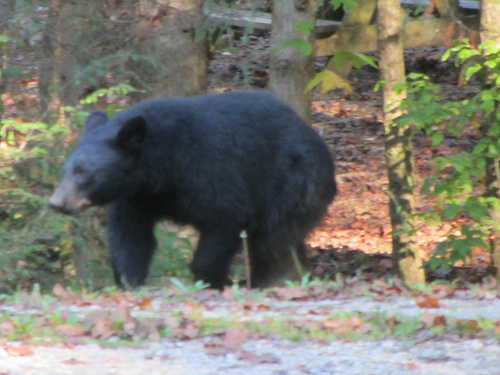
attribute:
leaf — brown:
[54, 281, 75, 302]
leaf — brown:
[92, 313, 115, 333]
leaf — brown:
[137, 296, 154, 315]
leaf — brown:
[218, 318, 247, 348]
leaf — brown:
[267, 284, 302, 296]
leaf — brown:
[413, 290, 440, 311]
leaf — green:
[272, 34, 299, 53]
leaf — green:
[454, 44, 479, 68]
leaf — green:
[467, 85, 493, 106]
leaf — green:
[470, 140, 491, 161]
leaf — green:
[465, 199, 485, 219]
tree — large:
[266, 2, 427, 289]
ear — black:
[117, 114, 146, 150]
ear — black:
[82, 108, 112, 136]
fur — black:
[70, 87, 340, 288]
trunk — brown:
[376, 3, 428, 281]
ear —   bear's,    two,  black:
[111, 115, 150, 154]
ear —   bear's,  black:
[81, 110, 111, 137]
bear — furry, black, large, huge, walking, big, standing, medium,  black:
[47, 90, 341, 292]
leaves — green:
[373, 39, 499, 277]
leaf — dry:
[365, 210, 376, 230]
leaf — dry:
[348, 196, 359, 203]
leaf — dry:
[344, 170, 372, 187]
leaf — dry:
[344, 147, 361, 157]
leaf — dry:
[424, 159, 431, 166]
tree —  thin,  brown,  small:
[266, 2, 499, 297]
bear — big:
[46, 92, 355, 282]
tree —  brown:
[337, 4, 429, 283]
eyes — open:
[22, 145, 130, 225]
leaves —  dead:
[317, 120, 394, 294]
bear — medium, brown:
[46, 82, 340, 312]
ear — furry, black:
[114, 115, 149, 153]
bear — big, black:
[51, 67, 372, 234]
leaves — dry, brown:
[341, 190, 393, 250]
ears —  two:
[82, 108, 147, 150]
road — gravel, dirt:
[5, 277, 495, 373]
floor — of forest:
[310, 98, 386, 250]